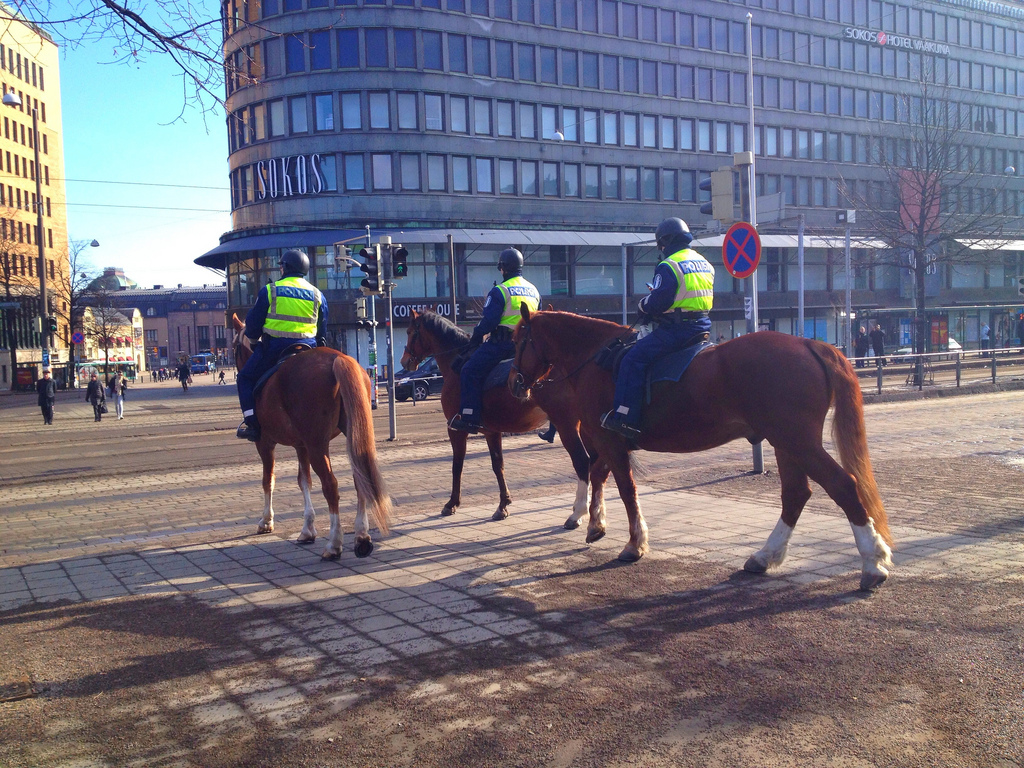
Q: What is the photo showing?
A: It is showing a street.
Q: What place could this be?
A: It is a street.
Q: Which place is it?
A: It is a street.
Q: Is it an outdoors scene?
A: Yes, it is outdoors.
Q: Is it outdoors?
A: Yes, it is outdoors.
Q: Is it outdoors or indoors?
A: It is outdoors.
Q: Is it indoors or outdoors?
A: It is outdoors.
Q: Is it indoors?
A: No, it is outdoors.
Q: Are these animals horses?
A: Yes, all the animals are horses.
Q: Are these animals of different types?
A: No, all the animals are horses.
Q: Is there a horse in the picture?
A: Yes, there is a horse.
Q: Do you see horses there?
A: Yes, there is a horse.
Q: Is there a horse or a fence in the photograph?
A: Yes, there is a horse.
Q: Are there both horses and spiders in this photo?
A: No, there is a horse but no spiders.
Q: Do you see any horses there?
A: Yes, there is a horse.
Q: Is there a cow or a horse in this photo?
A: Yes, there is a horse.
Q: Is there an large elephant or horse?
A: Yes, there is a large horse.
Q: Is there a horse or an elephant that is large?
A: Yes, the horse is large.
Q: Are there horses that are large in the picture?
A: Yes, there is a large horse.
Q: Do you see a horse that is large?
A: Yes, there is a horse that is large.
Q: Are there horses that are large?
A: Yes, there is a horse that is large.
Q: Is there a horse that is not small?
A: Yes, there is a large horse.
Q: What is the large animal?
A: The animal is a horse.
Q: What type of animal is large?
A: The animal is a horse.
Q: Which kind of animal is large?
A: The animal is a horse.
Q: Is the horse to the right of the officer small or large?
A: The horse is large.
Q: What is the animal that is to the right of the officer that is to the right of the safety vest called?
A: The animal is a horse.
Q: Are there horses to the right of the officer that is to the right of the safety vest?
A: Yes, there is a horse to the right of the officer.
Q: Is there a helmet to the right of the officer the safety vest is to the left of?
A: No, there is a horse to the right of the officer.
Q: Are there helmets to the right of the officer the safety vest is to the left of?
A: No, there is a horse to the right of the officer.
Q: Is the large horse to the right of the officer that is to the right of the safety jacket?
A: Yes, the horse is to the right of the officer.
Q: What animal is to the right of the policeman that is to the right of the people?
A: The animal is a horse.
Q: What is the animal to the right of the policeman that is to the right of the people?
A: The animal is a horse.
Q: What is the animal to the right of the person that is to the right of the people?
A: The animal is a horse.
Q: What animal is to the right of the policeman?
A: The animal is a horse.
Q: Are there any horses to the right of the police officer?
A: Yes, there is a horse to the right of the police officer.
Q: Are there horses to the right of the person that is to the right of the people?
A: Yes, there is a horse to the right of the police officer.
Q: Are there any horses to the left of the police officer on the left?
A: No, the horse is to the right of the policeman.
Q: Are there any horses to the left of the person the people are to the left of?
A: No, the horse is to the right of the policeman.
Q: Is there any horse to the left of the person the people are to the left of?
A: No, the horse is to the right of the policeman.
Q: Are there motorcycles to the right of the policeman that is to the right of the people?
A: No, there is a horse to the right of the police officer.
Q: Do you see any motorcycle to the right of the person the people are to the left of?
A: No, there is a horse to the right of the police officer.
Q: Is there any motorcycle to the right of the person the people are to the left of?
A: No, there is a horse to the right of the police officer.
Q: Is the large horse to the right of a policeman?
A: Yes, the horse is to the right of a policeman.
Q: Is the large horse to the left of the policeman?
A: No, the horse is to the right of the policeman.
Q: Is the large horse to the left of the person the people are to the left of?
A: No, the horse is to the right of the policeman.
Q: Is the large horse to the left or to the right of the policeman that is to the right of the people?
A: The horse is to the right of the policeman.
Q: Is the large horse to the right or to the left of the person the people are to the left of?
A: The horse is to the right of the policeman.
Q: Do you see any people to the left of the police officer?
A: Yes, there are people to the left of the police officer.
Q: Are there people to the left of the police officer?
A: Yes, there are people to the left of the police officer.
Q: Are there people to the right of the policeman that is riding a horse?
A: No, the people are to the left of the policeman.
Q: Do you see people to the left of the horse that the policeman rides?
A: Yes, there are people to the left of the horse.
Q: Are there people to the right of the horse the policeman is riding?
A: No, the people are to the left of the horse.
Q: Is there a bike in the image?
A: No, there are no bikes.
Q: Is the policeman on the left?
A: Yes, the policeman is on the left of the image.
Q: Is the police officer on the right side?
A: No, the police officer is on the left of the image.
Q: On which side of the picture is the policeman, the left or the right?
A: The policeman is on the left of the image.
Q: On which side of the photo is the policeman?
A: The policeman is on the left of the image.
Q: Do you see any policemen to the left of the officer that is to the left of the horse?
A: Yes, there is a policeman to the left of the officer.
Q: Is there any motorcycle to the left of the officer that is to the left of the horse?
A: No, there is a policeman to the left of the officer.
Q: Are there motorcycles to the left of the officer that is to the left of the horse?
A: No, there is a policeman to the left of the officer.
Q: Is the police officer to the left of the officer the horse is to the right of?
A: Yes, the police officer is to the left of the officer.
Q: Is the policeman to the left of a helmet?
A: No, the policeman is to the left of the officer.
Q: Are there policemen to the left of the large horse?
A: Yes, there is a policeman to the left of the horse.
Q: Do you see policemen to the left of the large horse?
A: Yes, there is a policeman to the left of the horse.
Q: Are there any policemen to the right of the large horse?
A: No, the policeman is to the left of the horse.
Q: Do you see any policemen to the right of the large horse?
A: No, the policeman is to the left of the horse.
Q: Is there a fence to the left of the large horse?
A: No, there is a policeman to the left of the horse.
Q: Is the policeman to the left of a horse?
A: Yes, the policeman is to the left of a horse.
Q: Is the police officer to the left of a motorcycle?
A: No, the police officer is to the left of a horse.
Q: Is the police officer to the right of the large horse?
A: No, the police officer is to the left of the horse.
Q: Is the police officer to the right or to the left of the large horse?
A: The police officer is to the left of the horse.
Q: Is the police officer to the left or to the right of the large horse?
A: The police officer is to the left of the horse.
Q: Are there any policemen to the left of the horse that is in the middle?
A: Yes, there is a policeman to the left of the horse.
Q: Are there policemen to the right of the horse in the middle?
A: No, the policeman is to the left of the horse.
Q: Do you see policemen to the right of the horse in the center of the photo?
A: No, the policeman is to the left of the horse.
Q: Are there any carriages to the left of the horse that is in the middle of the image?
A: No, there is a policeman to the left of the horse.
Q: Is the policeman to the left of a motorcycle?
A: No, the policeman is to the left of a horse.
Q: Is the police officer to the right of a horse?
A: No, the police officer is to the left of a horse.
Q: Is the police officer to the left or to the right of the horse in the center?
A: The police officer is to the left of the horse.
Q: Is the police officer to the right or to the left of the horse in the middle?
A: The police officer is to the left of the horse.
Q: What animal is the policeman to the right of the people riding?
A: The police officer is riding a horse.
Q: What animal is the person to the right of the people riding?
A: The police officer is riding a horse.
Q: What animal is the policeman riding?
A: The police officer is riding a horse.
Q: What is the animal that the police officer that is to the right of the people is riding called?
A: The animal is a horse.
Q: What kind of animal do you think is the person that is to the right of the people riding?
A: The police officer is riding a horse.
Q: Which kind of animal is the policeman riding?
A: The police officer is riding a horse.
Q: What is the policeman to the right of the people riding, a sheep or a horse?
A: The police officer is riding a horse.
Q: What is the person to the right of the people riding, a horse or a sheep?
A: The police officer is riding a horse.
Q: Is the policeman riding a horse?
A: Yes, the policeman is riding a horse.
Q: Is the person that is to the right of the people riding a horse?
A: Yes, the policeman is riding a horse.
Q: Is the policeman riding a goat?
A: No, the policeman is riding a horse.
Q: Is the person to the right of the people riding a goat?
A: No, the policeman is riding a horse.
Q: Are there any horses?
A: Yes, there is a horse.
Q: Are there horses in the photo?
A: Yes, there is a horse.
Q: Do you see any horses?
A: Yes, there is a horse.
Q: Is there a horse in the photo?
A: Yes, there is a horse.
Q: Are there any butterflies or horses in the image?
A: Yes, there is a horse.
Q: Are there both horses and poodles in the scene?
A: No, there is a horse but no poodles.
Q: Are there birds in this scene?
A: No, there are no birds.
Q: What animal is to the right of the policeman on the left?
A: The animal is a horse.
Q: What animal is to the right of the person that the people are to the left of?
A: The animal is a horse.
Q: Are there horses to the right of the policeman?
A: Yes, there is a horse to the right of the policeman.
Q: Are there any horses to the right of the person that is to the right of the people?
A: Yes, there is a horse to the right of the policeman.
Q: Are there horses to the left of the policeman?
A: No, the horse is to the right of the policeman.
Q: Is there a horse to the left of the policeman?
A: No, the horse is to the right of the policeman.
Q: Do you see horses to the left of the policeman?
A: No, the horse is to the right of the policeman.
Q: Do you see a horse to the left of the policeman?
A: No, the horse is to the right of the policeman.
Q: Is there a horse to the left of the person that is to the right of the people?
A: No, the horse is to the right of the policeman.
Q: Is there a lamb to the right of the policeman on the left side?
A: No, there is a horse to the right of the police officer.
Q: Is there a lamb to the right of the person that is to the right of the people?
A: No, there is a horse to the right of the police officer.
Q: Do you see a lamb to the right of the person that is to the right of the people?
A: No, there is a horse to the right of the police officer.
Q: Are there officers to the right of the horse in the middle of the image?
A: Yes, there is an officer to the right of the horse.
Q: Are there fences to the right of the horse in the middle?
A: No, there is an officer to the right of the horse.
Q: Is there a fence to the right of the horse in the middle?
A: No, there is an officer to the right of the horse.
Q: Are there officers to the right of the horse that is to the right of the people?
A: Yes, there is an officer to the right of the horse.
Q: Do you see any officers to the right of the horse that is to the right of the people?
A: Yes, there is an officer to the right of the horse.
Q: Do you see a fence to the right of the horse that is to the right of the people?
A: No, there is an officer to the right of the horse.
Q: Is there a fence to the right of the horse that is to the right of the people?
A: No, there is an officer to the right of the horse.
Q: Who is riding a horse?
A: The officer is riding a horse.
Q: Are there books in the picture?
A: No, there are no books.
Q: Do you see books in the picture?
A: No, there are no books.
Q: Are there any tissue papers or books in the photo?
A: No, there are no books or tissue papers.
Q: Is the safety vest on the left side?
A: Yes, the safety vest is on the left of the image.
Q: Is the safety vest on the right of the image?
A: No, the safety vest is on the left of the image.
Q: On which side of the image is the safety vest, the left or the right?
A: The safety vest is on the left of the image.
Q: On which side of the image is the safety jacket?
A: The safety jacket is on the left of the image.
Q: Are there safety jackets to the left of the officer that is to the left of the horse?
A: Yes, there is a safety jacket to the left of the officer.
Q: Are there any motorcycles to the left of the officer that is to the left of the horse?
A: No, there is a safety jacket to the left of the officer.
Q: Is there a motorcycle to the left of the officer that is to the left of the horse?
A: No, there is a safety jacket to the left of the officer.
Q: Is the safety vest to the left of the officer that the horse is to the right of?
A: Yes, the safety vest is to the left of the officer.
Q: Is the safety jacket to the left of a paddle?
A: No, the safety jacket is to the left of the officer.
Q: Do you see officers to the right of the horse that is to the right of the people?
A: Yes, there is an officer to the right of the horse.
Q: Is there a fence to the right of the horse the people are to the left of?
A: No, there is an officer to the right of the horse.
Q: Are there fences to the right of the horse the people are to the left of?
A: No, there is an officer to the right of the horse.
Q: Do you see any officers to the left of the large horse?
A: Yes, there is an officer to the left of the horse.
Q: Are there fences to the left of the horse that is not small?
A: No, there is an officer to the left of the horse.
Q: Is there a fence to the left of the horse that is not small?
A: No, there is an officer to the left of the horse.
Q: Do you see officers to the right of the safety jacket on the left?
A: Yes, there is an officer to the right of the safety vest.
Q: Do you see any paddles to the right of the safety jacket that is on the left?
A: No, there is an officer to the right of the safety vest.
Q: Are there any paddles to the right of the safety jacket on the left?
A: No, there is an officer to the right of the safety vest.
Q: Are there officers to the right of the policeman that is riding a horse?
A: Yes, there is an officer to the right of the policeman.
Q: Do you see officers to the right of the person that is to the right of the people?
A: Yes, there is an officer to the right of the policeman.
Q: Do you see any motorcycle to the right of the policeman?
A: No, there is an officer to the right of the policeman.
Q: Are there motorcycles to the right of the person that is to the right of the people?
A: No, there is an officer to the right of the policeman.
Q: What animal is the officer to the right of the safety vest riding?
A: The officer is riding a horse.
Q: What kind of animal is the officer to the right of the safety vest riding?
A: The officer is riding a horse.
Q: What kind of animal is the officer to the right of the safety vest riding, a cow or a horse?
A: The officer is riding a horse.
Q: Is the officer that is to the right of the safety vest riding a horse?
A: Yes, the officer is riding a horse.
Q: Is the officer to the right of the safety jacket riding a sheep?
A: No, the officer is riding a horse.